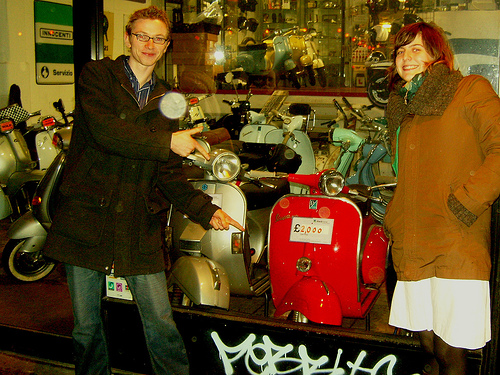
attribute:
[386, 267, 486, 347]
skirt — white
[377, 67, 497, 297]
jacket — brown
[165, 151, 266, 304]
motorcycle — silver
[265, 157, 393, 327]
scooter — red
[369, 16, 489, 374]
woman — standing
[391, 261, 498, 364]
skirt — white 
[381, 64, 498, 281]
coat — light brown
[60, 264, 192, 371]
jeans — blue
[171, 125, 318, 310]
scooter — vintage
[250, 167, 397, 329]
moped — red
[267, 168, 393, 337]
motorcycle — red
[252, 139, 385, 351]
scooter — red , vintage 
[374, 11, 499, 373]
people — posing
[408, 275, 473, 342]
skirt — white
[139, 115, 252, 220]
hand — shaped like a gun,  The right ,  man's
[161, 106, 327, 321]
motorcycle — silver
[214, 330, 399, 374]
graffiti — white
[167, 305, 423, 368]
panel — black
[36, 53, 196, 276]
jacket — brown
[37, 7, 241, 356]
man — standing, pointing